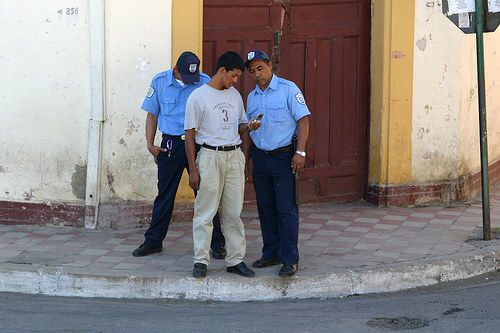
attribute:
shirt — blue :
[140, 68, 215, 140]